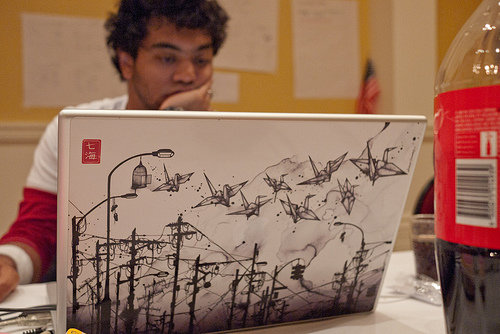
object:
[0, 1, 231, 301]
man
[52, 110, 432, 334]
laptop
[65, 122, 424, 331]
design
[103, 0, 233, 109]
head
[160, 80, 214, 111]
hand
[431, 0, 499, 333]
bottle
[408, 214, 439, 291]
glass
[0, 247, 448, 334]
table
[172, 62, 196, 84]
nose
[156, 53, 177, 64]
eye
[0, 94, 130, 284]
shirt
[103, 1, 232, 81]
hair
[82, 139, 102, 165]
symbol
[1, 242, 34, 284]
wristband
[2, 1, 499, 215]
wall